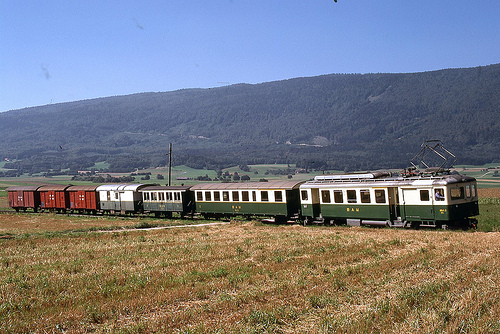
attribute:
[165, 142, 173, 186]
pole — brown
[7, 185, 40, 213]
train car — red, caboose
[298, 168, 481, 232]
train car — green, white, engine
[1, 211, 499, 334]
field — grassy, green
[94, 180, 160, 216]
train car — white, gray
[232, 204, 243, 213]
sign — yellow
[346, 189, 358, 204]
window — open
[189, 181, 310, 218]
train car — green, white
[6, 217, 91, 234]
dirt — brown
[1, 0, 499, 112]
sky — blue, clear, white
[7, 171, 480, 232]
train — long, passing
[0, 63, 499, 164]
hill — covered with trees, distant, green trees, background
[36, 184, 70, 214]
train car — red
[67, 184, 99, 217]
train car — red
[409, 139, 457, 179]
object — metal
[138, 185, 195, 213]
train car — grey, white